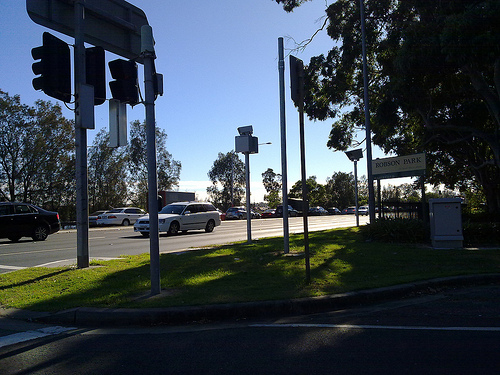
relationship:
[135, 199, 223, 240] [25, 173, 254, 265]
car traveling on road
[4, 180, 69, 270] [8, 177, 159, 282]
car on on road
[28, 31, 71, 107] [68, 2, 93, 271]
light on pole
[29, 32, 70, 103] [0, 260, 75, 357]
traffic light at intersection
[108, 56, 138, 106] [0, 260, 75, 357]
traffic light at intersection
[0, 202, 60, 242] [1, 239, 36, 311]
car on intersection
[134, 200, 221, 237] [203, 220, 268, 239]
car on road